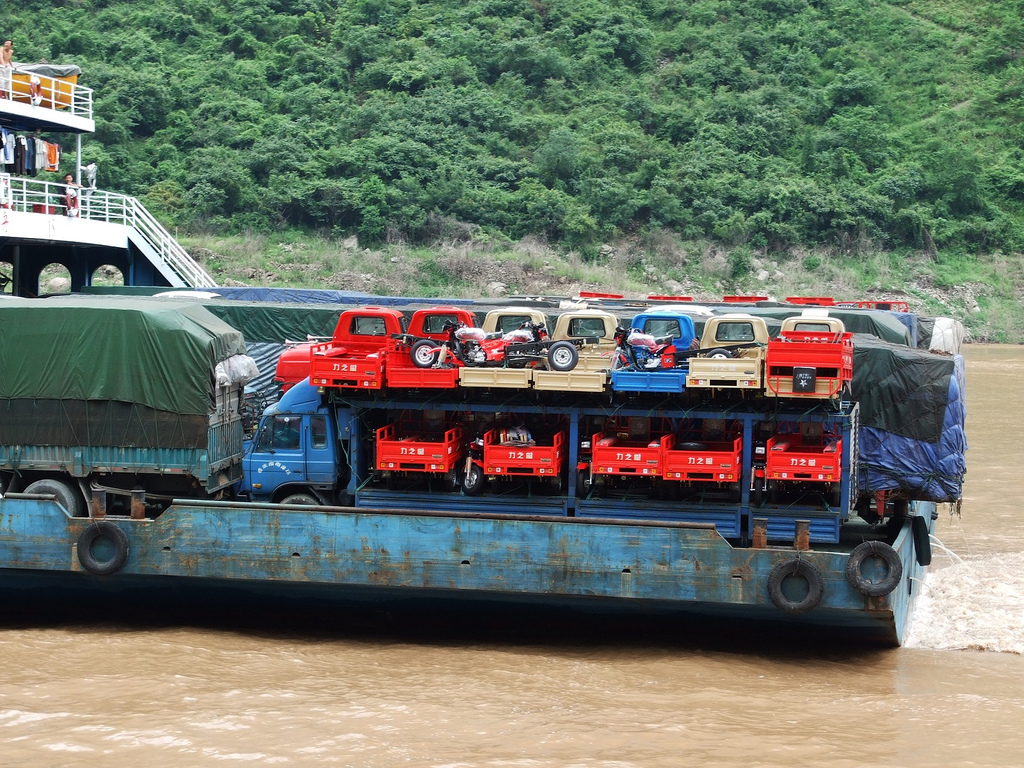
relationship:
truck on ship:
[233, 307, 870, 542] [0, 58, 968, 646]